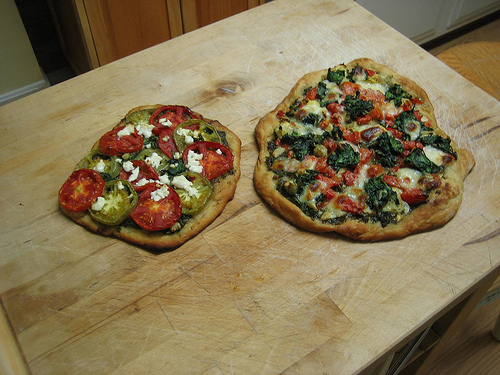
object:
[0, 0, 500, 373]
table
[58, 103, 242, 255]
pizza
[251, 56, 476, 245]
pizza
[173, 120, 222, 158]
tomato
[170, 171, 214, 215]
tomato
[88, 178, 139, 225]
tomato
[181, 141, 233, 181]
tomato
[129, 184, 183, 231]
tomato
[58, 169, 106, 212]
tomato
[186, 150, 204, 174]
feta cheese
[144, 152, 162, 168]
feta cheese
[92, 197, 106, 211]
feta cheese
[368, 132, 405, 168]
spinach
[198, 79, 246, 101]
spot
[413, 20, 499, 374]
floor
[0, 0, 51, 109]
wall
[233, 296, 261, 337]
line